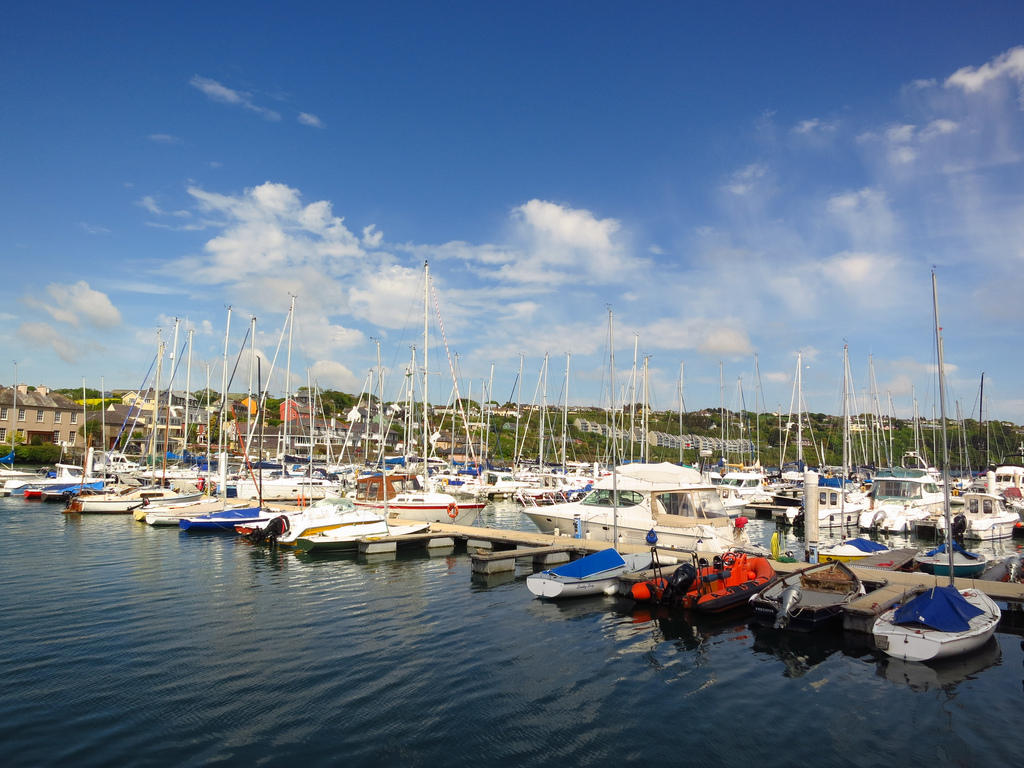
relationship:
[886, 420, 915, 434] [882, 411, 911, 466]
leaves on tree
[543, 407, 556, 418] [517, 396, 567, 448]
leaves on tree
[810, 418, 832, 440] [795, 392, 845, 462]
leaves on tree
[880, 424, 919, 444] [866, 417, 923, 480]
leaves on tree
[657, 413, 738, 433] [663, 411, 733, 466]
leaves on tree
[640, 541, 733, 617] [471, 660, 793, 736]
boat in water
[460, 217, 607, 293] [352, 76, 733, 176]
cloud in sky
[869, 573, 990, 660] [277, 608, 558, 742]
boat in water